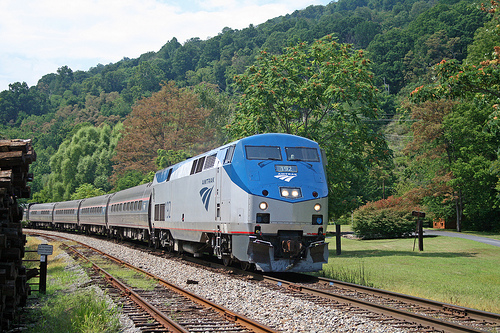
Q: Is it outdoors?
A: Yes, it is outdoors.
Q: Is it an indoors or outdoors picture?
A: It is outdoors.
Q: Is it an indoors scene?
A: No, it is outdoors.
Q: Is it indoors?
A: No, it is outdoors.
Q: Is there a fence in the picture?
A: No, there are no fences.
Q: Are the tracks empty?
A: Yes, the tracks are empty.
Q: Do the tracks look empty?
A: Yes, the tracks are empty.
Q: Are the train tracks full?
A: No, the train tracks are empty.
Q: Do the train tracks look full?
A: No, the train tracks are empty.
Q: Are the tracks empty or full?
A: The tracks are empty.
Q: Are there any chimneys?
A: No, there are no chimneys.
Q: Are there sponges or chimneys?
A: No, there are no chimneys or sponges.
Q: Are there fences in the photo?
A: No, there are no fences.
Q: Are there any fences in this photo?
A: No, there are no fences.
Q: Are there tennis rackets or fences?
A: No, there are no fences or tennis rackets.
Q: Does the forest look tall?
A: Yes, the forest is tall.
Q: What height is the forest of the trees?
A: The forest is tall.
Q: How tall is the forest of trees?
A: The forest is tall.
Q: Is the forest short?
A: No, the forest is tall.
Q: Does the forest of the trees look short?
A: No, the forest is tall.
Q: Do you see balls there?
A: No, there are no balls.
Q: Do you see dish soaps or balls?
A: No, there are no balls or dish soaps.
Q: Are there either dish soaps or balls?
A: No, there are no balls or dish soaps.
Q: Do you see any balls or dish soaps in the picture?
A: No, there are no balls or dish soaps.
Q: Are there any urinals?
A: No, there are no urinals.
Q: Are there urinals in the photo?
A: No, there are no urinals.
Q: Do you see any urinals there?
A: No, there are no urinals.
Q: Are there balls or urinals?
A: No, there are no urinals or balls.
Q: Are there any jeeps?
A: No, there are no jeeps.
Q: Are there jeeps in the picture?
A: No, there are no jeeps.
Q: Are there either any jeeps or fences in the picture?
A: No, there are no jeeps or fences.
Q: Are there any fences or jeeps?
A: No, there are no jeeps or fences.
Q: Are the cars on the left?
A: Yes, the cars are on the left of the image.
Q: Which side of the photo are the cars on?
A: The cars are on the left of the image.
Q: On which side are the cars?
A: The cars are on the left of the image.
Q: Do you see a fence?
A: No, there are no fences.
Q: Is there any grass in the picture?
A: Yes, there is grass.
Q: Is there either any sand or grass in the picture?
A: Yes, there is grass.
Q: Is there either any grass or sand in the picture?
A: Yes, there is grass.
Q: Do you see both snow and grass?
A: No, there is grass but no snow.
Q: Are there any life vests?
A: No, there are no life vests.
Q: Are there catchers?
A: No, there are no catchers.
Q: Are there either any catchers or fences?
A: No, there are no catchers or fences.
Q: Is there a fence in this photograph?
A: No, there are no fences.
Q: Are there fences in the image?
A: No, there are no fences.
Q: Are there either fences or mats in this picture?
A: No, there are no fences or mats.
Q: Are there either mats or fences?
A: No, there are no fences or mats.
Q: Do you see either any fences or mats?
A: No, there are no fences or mats.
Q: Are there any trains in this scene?
A: Yes, there is a train.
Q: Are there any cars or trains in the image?
A: Yes, there is a train.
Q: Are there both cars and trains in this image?
A: Yes, there are both a train and cars.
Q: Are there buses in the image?
A: No, there are no buses.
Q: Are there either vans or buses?
A: No, there are no buses or vans.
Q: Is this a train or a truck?
A: This is a train.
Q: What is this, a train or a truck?
A: This is a train.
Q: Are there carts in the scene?
A: No, there are no carts.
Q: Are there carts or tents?
A: No, there are no carts or tents.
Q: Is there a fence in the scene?
A: No, there are no fences.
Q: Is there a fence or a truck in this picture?
A: No, there are no fences or trucks.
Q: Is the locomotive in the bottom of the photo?
A: Yes, the locomotive is in the bottom of the image.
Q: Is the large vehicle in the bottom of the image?
A: Yes, the locomotive is in the bottom of the image.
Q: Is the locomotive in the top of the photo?
A: No, the locomotive is in the bottom of the image.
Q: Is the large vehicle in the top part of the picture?
A: No, the locomotive is in the bottom of the image.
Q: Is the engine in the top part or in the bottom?
A: The engine is in the bottom of the image.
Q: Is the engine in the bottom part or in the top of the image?
A: The engine is in the bottom of the image.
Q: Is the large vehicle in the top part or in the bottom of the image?
A: The engine is in the bottom of the image.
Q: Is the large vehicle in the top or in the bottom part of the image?
A: The engine is in the bottom of the image.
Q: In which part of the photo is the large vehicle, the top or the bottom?
A: The engine is in the bottom of the image.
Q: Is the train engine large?
A: Yes, the train engine is large.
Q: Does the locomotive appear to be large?
A: Yes, the locomotive is large.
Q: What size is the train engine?
A: The train engine is large.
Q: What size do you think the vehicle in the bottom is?
A: The train engine is large.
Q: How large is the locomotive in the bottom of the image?
A: The train engine is large.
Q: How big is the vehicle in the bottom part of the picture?
A: The train engine is large.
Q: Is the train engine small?
A: No, the train engine is large.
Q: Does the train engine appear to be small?
A: No, the train engine is large.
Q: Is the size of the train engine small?
A: No, the train engine is large.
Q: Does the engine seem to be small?
A: No, the engine is large.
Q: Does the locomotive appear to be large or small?
A: The locomotive is large.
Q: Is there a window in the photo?
A: Yes, there are windows.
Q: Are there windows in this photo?
A: Yes, there are windows.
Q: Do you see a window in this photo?
A: Yes, there are windows.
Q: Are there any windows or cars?
A: Yes, there are windows.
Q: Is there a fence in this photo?
A: No, there are no fences.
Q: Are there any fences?
A: No, there are no fences.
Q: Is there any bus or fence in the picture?
A: No, there are no fences or buses.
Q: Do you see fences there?
A: No, there are no fences.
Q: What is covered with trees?
A: The hill side is covered with trees.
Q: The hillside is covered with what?
A: The hillside is covered with trees.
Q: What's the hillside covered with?
A: The hillside is covered with trees.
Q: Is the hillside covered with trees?
A: Yes, the hillside is covered with trees.